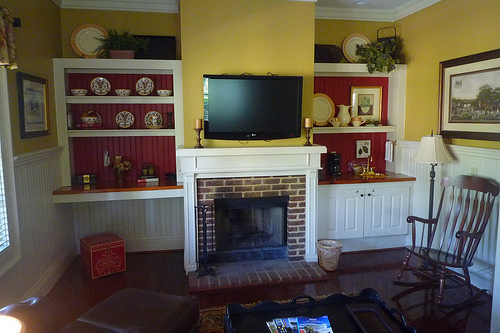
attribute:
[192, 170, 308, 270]
fireplace — brick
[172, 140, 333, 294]
mantlepiece — white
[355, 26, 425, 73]
basket — small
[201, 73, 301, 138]
tv — black, flat screen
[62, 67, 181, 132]
dishes — decorative 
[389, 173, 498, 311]
rocking chair — brown, wooden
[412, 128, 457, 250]
lamp — beige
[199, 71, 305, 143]
tv — flat screen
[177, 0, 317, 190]
wall — yellow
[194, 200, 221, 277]
tools — black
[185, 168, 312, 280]
fireplace — brick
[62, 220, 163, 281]
gold box — red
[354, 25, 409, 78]
plant — green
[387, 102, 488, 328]
lamp — tan, ornate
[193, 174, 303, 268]
fireplace — brick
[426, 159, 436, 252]
base — wood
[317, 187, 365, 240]
door — white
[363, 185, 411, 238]
door — white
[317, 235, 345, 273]
waste basket — small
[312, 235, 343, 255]
liner — plastic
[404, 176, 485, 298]
chair — rocking 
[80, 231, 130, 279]
box — white, red